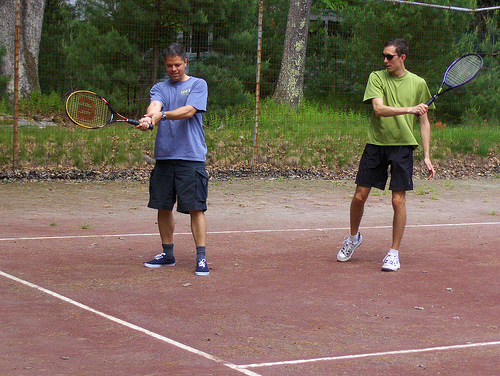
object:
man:
[133, 44, 211, 276]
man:
[334, 38, 437, 272]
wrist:
[144, 114, 158, 122]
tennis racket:
[64, 90, 154, 131]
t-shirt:
[361, 68, 436, 147]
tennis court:
[1, 218, 498, 375]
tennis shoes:
[193, 255, 211, 276]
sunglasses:
[380, 53, 403, 59]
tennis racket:
[413, 52, 483, 118]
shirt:
[150, 76, 208, 162]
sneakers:
[335, 232, 364, 263]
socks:
[160, 242, 174, 257]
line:
[237, 339, 499, 369]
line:
[0, 271, 234, 370]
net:
[16, 2, 262, 170]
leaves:
[415, 157, 499, 180]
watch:
[160, 110, 168, 121]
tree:
[270, 0, 310, 110]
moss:
[288, 67, 301, 103]